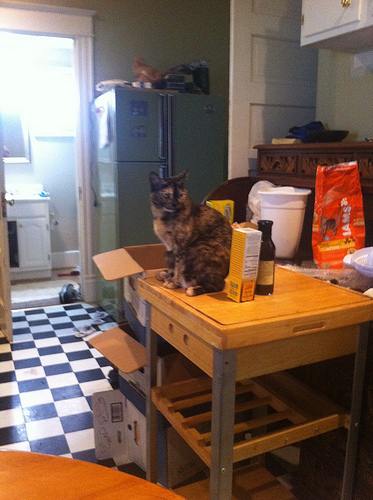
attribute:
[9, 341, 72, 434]
floor — tiles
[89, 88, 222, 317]
fridge — green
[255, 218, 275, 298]
bottle — glass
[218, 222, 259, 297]
box — yellow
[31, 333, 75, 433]
floor — tiles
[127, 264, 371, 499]
cart — wooden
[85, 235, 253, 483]
boxes — stacked, cardboard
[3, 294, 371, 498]
floor — white, black, tiles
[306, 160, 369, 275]
bag — orange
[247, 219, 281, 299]
bottle — brown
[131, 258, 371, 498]
table — wooden, breakfast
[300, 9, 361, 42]
door — white, cabinet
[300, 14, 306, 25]
knob — gold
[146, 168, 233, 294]
cat — black, brown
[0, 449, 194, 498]
table — wooden